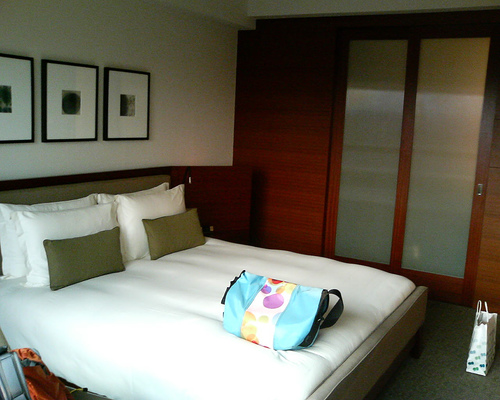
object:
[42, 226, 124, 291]
pillow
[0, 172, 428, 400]
bed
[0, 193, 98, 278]
pillow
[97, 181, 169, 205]
pillow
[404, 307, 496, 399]
carpet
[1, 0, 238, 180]
wall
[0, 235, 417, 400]
sheets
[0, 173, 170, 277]
headboard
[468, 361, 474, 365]
blue rectangles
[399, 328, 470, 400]
ground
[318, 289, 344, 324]
handles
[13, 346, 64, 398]
orange backpack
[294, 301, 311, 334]
blue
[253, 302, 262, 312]
white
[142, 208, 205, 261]
pillow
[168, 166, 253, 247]
cabinet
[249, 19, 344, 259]
wall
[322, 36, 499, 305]
door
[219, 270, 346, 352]
bag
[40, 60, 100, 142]
photos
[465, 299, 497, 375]
bag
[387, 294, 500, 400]
floor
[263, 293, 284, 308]
circle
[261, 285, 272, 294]
circle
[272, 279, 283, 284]
circle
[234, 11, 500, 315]
closet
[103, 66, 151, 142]
picture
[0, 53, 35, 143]
picture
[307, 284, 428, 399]
footboard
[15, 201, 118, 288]
pillow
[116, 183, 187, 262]
pillow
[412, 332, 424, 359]
foot